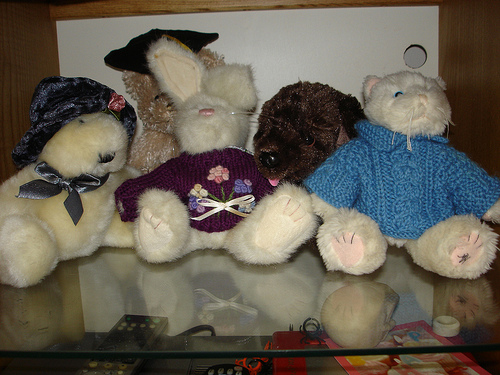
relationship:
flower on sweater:
[233, 177, 253, 193] [113, 147, 278, 232]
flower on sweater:
[188, 182, 208, 201] [122, 150, 272, 234]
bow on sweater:
[188, 192, 255, 221] [113, 147, 278, 232]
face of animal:
[249, 74, 361, 189] [298, 69, 500, 283]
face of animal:
[363, 68, 453, 137] [298, 69, 500, 283]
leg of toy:
[316, 207, 386, 275] [303, 62, 498, 282]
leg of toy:
[408, 213, 498, 278] [303, 62, 498, 282]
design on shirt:
[190, 159, 257, 226] [114, 148, 272, 238]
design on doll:
[206, 164, 230, 202] [157, 69, 309, 267]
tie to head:
[14, 160, 114, 233] [17, 75, 142, 192]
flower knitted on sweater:
[188, 182, 209, 200] [113, 147, 278, 232]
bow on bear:
[14, 159, 104, 227] [0, 73, 142, 284]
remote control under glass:
[72, 302, 176, 374] [2, 234, 497, 353]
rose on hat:
[104, 87, 131, 111] [13, 59, 150, 153]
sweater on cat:
[307, 120, 499, 235] [310, 71, 499, 280]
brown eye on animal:
[298, 132, 319, 149] [298, 69, 500, 283]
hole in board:
[401, 40, 430, 72] [53, 3, 439, 336]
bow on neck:
[0, 161, 117, 212] [36, 157, 114, 187]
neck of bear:
[36, 157, 114, 187] [7, 73, 152, 289]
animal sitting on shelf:
[7, 78, 145, 284] [5, 6, 495, 356]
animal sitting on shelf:
[298, 69, 500, 283] [5, 6, 495, 356]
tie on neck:
[14, 160, 110, 225] [33, 158, 111, 195]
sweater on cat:
[307, 120, 499, 235] [0, 74, 143, 291]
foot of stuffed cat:
[314, 221, 389, 266] [311, 35, 498, 274]